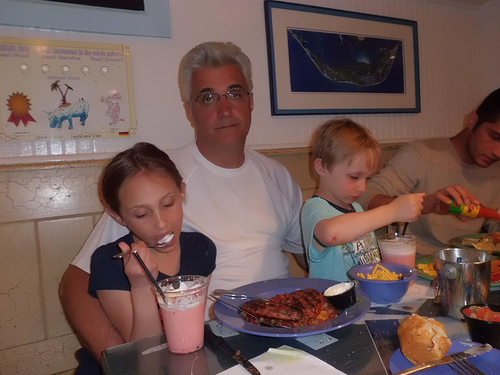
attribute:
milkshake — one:
[155, 272, 211, 353]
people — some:
[90, 73, 486, 333]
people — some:
[67, 34, 486, 325]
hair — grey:
[181, 42, 239, 68]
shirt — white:
[173, 146, 293, 276]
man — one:
[182, 44, 269, 154]